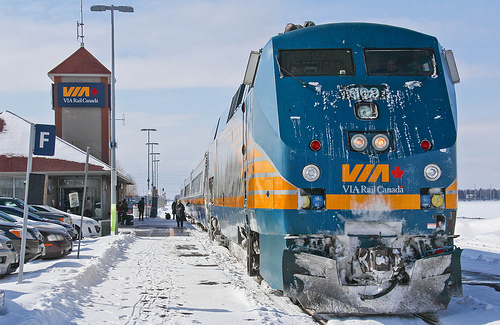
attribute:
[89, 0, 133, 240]
street light — tall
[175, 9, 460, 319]
train — blue, yellow, stopped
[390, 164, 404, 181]
leaf — red, maple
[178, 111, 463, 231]
lines — yellow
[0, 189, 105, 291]
cars — parked, row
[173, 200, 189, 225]
person — walking, standing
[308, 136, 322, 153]
light — red, circular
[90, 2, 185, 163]
lights — row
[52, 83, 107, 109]
sign — blue, multi colored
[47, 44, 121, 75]
roof — pointed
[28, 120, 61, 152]
sign — blue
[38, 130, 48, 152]
letter — white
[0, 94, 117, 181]
roof — red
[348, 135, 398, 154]
lights — on